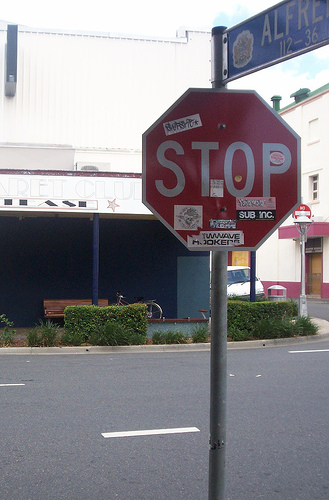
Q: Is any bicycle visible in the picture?
A: Yes, there is a bicycle.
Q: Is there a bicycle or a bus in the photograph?
A: Yes, there is a bicycle.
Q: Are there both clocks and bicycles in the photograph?
A: No, there is a bicycle but no clocks.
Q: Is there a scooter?
A: No, there are no scooters.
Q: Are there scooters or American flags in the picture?
A: No, there are no scooters or American flags.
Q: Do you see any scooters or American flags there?
A: No, there are no scooters or American flags.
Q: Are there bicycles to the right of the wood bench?
A: Yes, there is a bicycle to the right of the bench.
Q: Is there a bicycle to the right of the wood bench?
A: Yes, there is a bicycle to the right of the bench.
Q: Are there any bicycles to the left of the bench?
A: No, the bicycle is to the right of the bench.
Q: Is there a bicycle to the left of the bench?
A: No, the bicycle is to the right of the bench.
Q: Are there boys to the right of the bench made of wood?
A: No, there is a bicycle to the right of the bench.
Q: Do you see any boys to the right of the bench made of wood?
A: No, there is a bicycle to the right of the bench.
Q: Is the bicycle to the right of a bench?
A: Yes, the bicycle is to the right of a bench.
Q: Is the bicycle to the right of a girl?
A: No, the bicycle is to the right of a bench.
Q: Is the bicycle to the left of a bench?
A: No, the bicycle is to the right of a bench.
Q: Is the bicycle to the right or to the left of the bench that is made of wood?
A: The bicycle is to the right of the bench.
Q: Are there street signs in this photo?
A: Yes, there is a street sign.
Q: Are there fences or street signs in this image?
A: Yes, there is a street sign.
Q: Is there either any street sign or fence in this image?
A: Yes, there is a street sign.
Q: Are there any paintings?
A: No, there are no paintings.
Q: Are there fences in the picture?
A: No, there are no fences.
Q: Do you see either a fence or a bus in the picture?
A: No, there are no fences or buses.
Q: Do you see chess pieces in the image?
A: No, there are no chess pieces.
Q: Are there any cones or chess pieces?
A: No, there are no chess pieces or cones.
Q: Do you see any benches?
A: Yes, there is a bench.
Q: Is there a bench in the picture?
A: Yes, there is a bench.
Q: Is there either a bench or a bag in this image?
A: Yes, there is a bench.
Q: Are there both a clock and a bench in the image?
A: No, there is a bench but no clocks.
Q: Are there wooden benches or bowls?
A: Yes, there is a wood bench.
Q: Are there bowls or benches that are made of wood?
A: Yes, the bench is made of wood.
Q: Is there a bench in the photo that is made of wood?
A: Yes, there is a bench that is made of wood.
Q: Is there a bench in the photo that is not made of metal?
A: Yes, there is a bench that is made of wood.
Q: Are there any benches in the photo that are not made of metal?
A: Yes, there is a bench that is made of wood.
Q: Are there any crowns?
A: No, there are no crowns.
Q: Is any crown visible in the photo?
A: No, there are no crowns.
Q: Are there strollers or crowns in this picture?
A: No, there are no crowns or strollers.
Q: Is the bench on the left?
A: Yes, the bench is on the left of the image.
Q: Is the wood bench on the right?
A: No, the bench is on the left of the image.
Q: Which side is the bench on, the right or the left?
A: The bench is on the left of the image.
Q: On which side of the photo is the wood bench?
A: The bench is on the left of the image.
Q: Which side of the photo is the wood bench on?
A: The bench is on the left of the image.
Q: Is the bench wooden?
A: Yes, the bench is wooden.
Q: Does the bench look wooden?
A: Yes, the bench is wooden.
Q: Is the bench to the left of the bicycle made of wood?
A: Yes, the bench is made of wood.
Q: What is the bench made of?
A: The bench is made of wood.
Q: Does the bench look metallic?
A: No, the bench is wooden.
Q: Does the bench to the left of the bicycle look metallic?
A: No, the bench is wooden.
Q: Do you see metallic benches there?
A: No, there is a bench but it is wooden.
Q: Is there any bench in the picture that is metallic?
A: No, there is a bench but it is wooden.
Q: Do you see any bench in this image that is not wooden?
A: No, there is a bench but it is wooden.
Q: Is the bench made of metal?
A: No, the bench is made of wood.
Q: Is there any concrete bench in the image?
A: No, there is a bench but it is made of wood.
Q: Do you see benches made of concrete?
A: No, there is a bench but it is made of wood.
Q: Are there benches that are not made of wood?
A: No, there is a bench but it is made of wood.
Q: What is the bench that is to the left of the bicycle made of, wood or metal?
A: The bench is made of wood.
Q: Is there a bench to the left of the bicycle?
A: Yes, there is a bench to the left of the bicycle.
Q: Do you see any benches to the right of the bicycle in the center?
A: No, the bench is to the left of the bicycle.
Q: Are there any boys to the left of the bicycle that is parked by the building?
A: No, there is a bench to the left of the bicycle.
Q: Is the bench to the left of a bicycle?
A: Yes, the bench is to the left of a bicycle.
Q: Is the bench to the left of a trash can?
A: No, the bench is to the left of a bicycle.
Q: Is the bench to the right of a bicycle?
A: No, the bench is to the left of a bicycle.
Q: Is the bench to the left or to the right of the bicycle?
A: The bench is to the left of the bicycle.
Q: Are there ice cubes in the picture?
A: No, there are no ice cubes.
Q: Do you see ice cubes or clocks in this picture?
A: No, there are no ice cubes or clocks.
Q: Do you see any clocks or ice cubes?
A: No, there are no ice cubes or clocks.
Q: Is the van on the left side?
A: No, the van is on the right of the image.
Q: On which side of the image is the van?
A: The van is on the right of the image.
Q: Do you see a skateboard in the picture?
A: No, there are no skateboards.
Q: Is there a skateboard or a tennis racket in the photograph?
A: No, there are no skateboards or rackets.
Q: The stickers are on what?
A: The stickers are on the sign.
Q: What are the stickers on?
A: The stickers are on the sign.